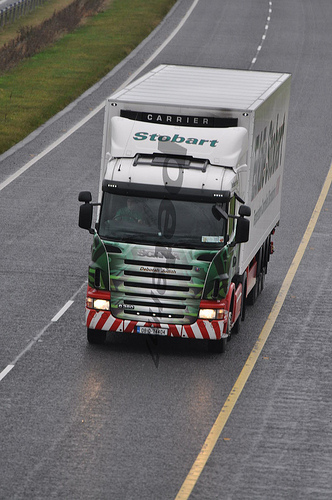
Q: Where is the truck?
A: Highway.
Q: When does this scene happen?
A: Daytime.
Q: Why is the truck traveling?
A: To make deliveries.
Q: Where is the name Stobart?
A: On top of the truck cab.